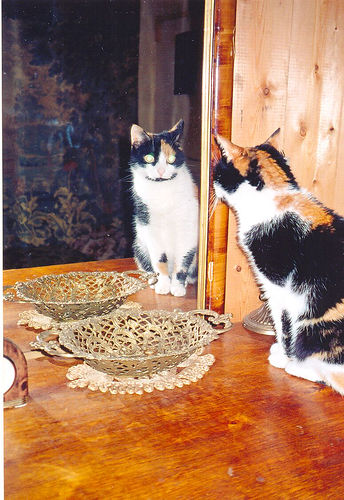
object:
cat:
[214, 132, 343, 396]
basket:
[54, 316, 230, 376]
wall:
[218, 0, 343, 340]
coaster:
[58, 365, 224, 392]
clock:
[0, 340, 33, 412]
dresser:
[3, 299, 343, 498]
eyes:
[142, 152, 155, 165]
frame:
[202, 0, 231, 325]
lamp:
[240, 273, 296, 341]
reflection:
[11, 245, 162, 309]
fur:
[283, 209, 330, 350]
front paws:
[170, 264, 188, 300]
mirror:
[7, 5, 198, 317]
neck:
[236, 186, 305, 222]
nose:
[155, 165, 169, 173]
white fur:
[239, 193, 274, 222]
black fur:
[271, 234, 332, 265]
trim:
[201, 0, 242, 322]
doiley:
[63, 365, 212, 392]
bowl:
[41, 303, 219, 373]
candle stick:
[245, 288, 279, 336]